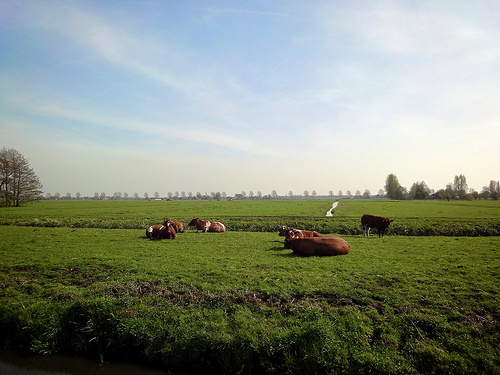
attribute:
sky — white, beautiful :
[71, 43, 468, 164]